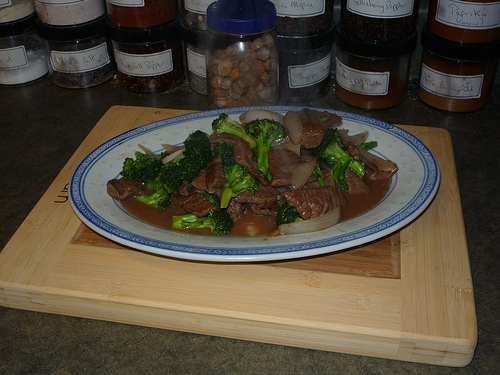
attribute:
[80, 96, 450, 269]
plate — china, blue, white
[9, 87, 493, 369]
board — brown, square, toned, wooden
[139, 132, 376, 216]
food — sliced, few, thin, green, brown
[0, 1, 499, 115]
jars — round, blue, old, closed, full, many, filled, covered, labeled, clear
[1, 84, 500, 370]
counter — green